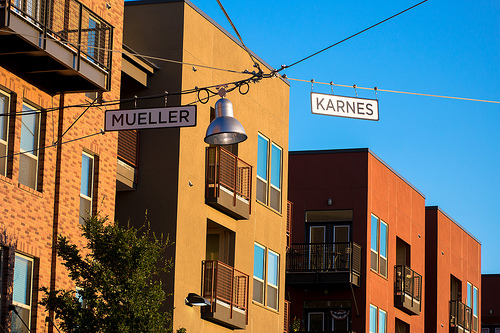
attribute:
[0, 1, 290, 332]
building — brick, brown, orange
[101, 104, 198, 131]
sign — white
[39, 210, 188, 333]
tree — large, green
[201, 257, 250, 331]
balcony — orange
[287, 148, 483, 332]
structure — orange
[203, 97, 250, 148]
lamp — hanging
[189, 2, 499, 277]
sky — blue